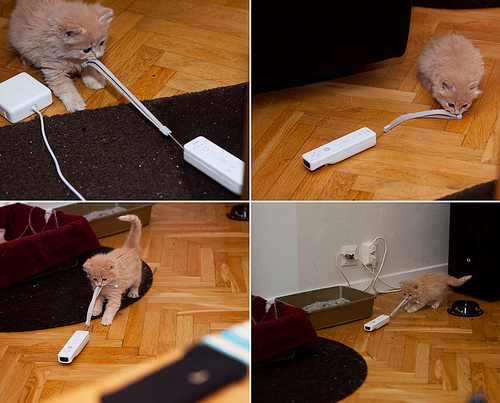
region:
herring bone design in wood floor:
[333, 300, 492, 393]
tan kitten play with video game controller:
[408, 22, 490, 126]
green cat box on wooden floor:
[268, 280, 385, 338]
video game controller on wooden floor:
[291, 120, 391, 186]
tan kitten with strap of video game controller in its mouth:
[68, 208, 157, 340]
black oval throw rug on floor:
[248, 327, 378, 394]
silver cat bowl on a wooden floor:
[436, 287, 488, 327]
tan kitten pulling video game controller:
[0, 5, 235, 191]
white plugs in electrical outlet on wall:
[330, 233, 393, 280]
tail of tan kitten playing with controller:
[111, 210, 149, 255]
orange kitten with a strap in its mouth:
[85, 213, 142, 330]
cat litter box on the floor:
[288, 288, 373, 318]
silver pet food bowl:
[451, 300, 482, 314]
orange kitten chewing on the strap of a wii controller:
[416, 30, 486, 122]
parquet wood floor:
[390, 322, 464, 394]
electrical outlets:
[341, 242, 381, 267]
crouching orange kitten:
[399, 269, 469, 308]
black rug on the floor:
[277, 358, 348, 391]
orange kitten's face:
[441, 75, 476, 113]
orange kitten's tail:
[118, 213, 143, 247]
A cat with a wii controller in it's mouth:
[8, 3, 249, 195]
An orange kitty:
[10, 4, 120, 109]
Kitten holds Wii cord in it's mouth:
[51, 0, 126, 82]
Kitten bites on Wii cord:
[421, 25, 483, 122]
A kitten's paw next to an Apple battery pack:
[0, 73, 106, 123]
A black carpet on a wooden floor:
[0, 53, 252, 199]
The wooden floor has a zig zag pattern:
[402, 325, 499, 396]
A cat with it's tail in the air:
[83, 212, 157, 322]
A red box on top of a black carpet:
[253, 293, 345, 398]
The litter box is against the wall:
[276, 284, 376, 326]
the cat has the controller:
[357, 263, 479, 354]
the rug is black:
[249, 326, 391, 401]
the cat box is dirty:
[268, 278, 378, 330]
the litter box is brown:
[269, 277, 378, 334]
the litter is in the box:
[274, 277, 382, 334]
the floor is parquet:
[0, 202, 245, 402]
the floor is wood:
[3, 204, 244, 401]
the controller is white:
[36, 277, 128, 373]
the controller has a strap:
[81, 278, 113, 330]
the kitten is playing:
[67, 209, 160, 336]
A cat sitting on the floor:
[10, 3, 117, 64]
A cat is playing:
[38, 261, 155, 362]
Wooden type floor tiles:
[152, 13, 218, 58]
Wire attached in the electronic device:
[10, 81, 59, 194]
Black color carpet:
[94, 140, 144, 172]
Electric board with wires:
[337, 236, 396, 285]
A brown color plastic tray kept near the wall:
[309, 290, 348, 317]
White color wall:
[277, 214, 324, 259]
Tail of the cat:
[113, 208, 156, 238]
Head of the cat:
[428, 75, 486, 116]